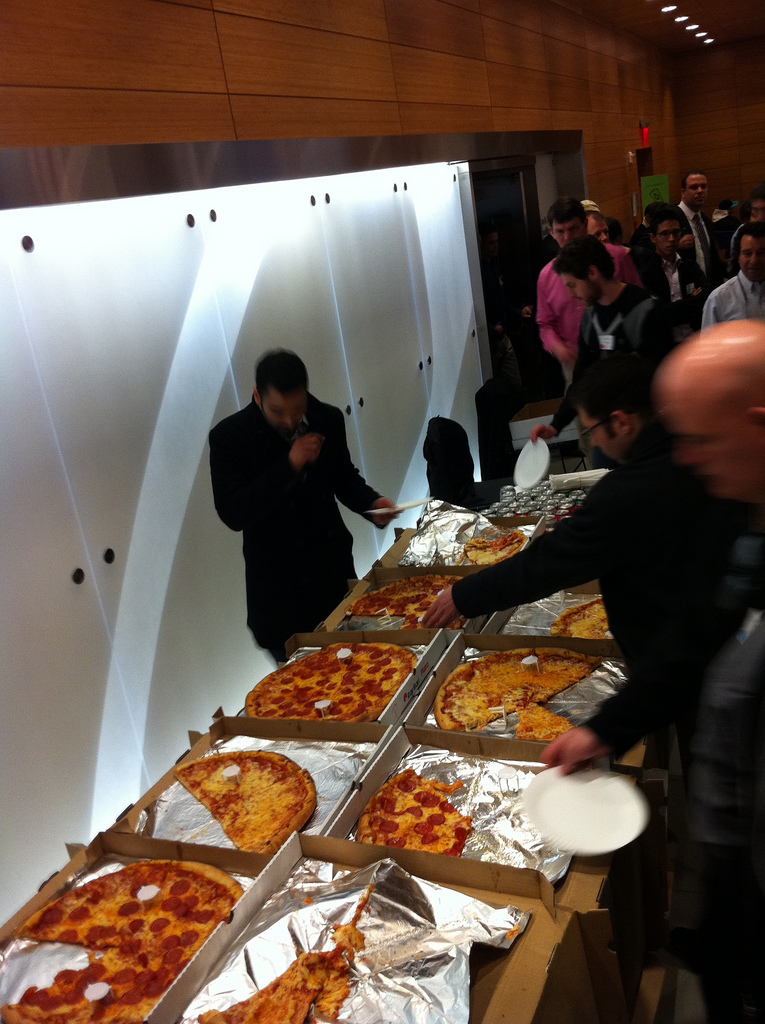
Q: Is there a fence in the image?
A: No, there are no fences.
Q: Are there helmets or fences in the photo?
A: No, there are no fences or helmets.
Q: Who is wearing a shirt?
A: The man is wearing a shirt.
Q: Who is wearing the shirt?
A: The man is wearing a shirt.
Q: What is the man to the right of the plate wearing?
A: The man is wearing a shirt.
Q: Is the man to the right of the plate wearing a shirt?
A: Yes, the man is wearing a shirt.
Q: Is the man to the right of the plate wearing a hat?
A: No, the man is wearing a shirt.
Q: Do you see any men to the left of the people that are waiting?
A: Yes, there is a man to the left of the people.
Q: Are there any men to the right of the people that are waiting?
A: No, the man is to the left of the people.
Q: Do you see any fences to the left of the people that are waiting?
A: No, there is a man to the left of the people.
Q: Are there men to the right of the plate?
A: Yes, there is a man to the right of the plate.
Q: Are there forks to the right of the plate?
A: No, there is a man to the right of the plate.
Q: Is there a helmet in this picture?
A: No, there are no helmets.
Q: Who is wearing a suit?
A: The man is wearing a suit.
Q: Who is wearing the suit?
A: The man is wearing a suit.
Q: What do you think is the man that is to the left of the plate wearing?
A: The man is wearing a suit.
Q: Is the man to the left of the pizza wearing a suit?
A: Yes, the man is wearing a suit.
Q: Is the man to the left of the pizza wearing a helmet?
A: No, the man is wearing a suit.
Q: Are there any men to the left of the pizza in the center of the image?
A: Yes, there is a man to the left of the pizza.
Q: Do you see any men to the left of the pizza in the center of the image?
A: Yes, there is a man to the left of the pizza.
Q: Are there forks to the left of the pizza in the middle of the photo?
A: No, there is a man to the left of the pizza.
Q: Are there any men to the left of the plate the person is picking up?
A: Yes, there is a man to the left of the plate.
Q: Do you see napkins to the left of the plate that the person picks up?
A: No, there is a man to the left of the plate.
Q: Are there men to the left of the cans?
A: Yes, there is a man to the left of the cans.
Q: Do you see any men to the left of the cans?
A: Yes, there is a man to the left of the cans.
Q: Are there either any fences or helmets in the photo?
A: No, there are no fences or helmets.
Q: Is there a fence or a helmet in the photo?
A: No, there are no fences or helmets.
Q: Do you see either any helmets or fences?
A: No, there are no fences or helmets.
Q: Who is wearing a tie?
A: The man is wearing a tie.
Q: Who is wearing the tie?
A: The man is wearing a tie.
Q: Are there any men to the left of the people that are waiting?
A: Yes, there is a man to the left of the people.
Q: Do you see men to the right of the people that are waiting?
A: No, the man is to the left of the people.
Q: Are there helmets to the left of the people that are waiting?
A: No, there is a man to the left of the people.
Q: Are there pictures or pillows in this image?
A: No, there are no pictures or pillows.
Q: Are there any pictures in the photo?
A: No, there are no pictures.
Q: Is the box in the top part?
A: No, the box is in the bottom of the image.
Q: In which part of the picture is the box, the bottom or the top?
A: The box is in the bottom of the image.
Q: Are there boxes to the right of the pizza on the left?
A: Yes, there is a box to the right of the pizza.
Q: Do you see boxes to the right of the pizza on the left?
A: Yes, there is a box to the right of the pizza.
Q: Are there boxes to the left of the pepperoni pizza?
A: No, the box is to the right of the pizza.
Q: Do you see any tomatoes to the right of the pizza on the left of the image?
A: No, there is a box to the right of the pizza.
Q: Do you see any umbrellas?
A: No, there are no umbrellas.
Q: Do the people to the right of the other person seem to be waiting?
A: Yes, the people are waiting.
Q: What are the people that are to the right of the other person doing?
A: The people are waiting.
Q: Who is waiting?
A: The people are waiting.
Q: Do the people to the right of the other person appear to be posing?
A: No, the people are waiting.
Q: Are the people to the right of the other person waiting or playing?
A: The people are waiting.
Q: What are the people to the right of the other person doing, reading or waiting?
A: The people are waiting.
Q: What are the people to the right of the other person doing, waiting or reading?
A: The people are waiting.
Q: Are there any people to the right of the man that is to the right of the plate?
A: Yes, there are people to the right of the man.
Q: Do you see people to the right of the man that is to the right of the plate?
A: Yes, there are people to the right of the man.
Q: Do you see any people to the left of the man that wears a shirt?
A: No, the people are to the right of the man.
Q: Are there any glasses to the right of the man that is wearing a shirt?
A: No, there are people to the right of the man.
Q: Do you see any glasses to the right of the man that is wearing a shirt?
A: No, there are people to the right of the man.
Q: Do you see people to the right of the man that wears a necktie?
A: Yes, there are people to the right of the man.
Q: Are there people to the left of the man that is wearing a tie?
A: No, the people are to the right of the man.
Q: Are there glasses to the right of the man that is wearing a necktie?
A: No, there are people to the right of the man.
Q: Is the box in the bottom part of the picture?
A: Yes, the box is in the bottom of the image.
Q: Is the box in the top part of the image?
A: No, the box is in the bottom of the image.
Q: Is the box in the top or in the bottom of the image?
A: The box is in the bottom of the image.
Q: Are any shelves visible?
A: No, there are no shelves.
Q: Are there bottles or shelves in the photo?
A: No, there are no shelves or bottles.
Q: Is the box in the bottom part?
A: Yes, the box is in the bottom of the image.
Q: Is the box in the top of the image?
A: No, the box is in the bottom of the image.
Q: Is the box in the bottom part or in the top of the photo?
A: The box is in the bottom of the image.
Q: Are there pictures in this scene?
A: No, there are no pictures.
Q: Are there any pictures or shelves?
A: No, there are no pictures or shelves.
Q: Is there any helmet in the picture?
A: No, there are no helmets.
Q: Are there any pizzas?
A: Yes, there is a pizza.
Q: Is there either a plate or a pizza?
A: Yes, there is a pizza.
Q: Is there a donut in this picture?
A: No, there are no donuts.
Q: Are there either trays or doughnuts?
A: No, there are no doughnuts or trays.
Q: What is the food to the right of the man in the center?
A: The food is a pizza.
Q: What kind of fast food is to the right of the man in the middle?
A: The food is a pizza.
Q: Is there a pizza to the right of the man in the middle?
A: Yes, there is a pizza to the right of the man.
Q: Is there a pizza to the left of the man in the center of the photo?
A: No, the pizza is to the right of the man.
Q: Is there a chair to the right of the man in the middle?
A: No, there is a pizza to the right of the man.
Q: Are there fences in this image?
A: No, there are no fences.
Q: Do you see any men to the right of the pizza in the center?
A: Yes, there is a man to the right of the pizza.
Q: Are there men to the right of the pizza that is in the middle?
A: Yes, there is a man to the right of the pizza.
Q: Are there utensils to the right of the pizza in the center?
A: No, there is a man to the right of the pizza.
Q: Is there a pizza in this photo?
A: Yes, there is a pizza.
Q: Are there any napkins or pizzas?
A: Yes, there is a pizza.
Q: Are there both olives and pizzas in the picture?
A: No, there is a pizza but no olives.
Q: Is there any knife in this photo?
A: No, there are no knives.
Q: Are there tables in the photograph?
A: Yes, there is a table.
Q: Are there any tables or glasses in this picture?
A: Yes, there is a table.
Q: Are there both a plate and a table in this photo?
A: Yes, there are both a table and a plate.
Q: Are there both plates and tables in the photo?
A: Yes, there are both a table and a plate.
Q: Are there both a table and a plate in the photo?
A: Yes, there are both a table and a plate.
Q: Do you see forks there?
A: No, there are no forks.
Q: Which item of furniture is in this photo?
A: The piece of furniture is a table.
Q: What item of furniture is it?
A: The piece of furniture is a table.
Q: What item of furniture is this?
A: This is a table.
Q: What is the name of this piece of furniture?
A: This is a table.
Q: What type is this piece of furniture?
A: This is a table.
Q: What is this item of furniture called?
A: This is a table.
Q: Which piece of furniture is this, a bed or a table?
A: This is a table.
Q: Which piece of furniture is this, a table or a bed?
A: This is a table.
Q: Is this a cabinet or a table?
A: This is a table.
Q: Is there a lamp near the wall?
A: No, there is a table near the wall.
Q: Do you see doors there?
A: Yes, there is a door.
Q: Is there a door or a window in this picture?
A: Yes, there is a door.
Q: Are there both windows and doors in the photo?
A: No, there is a door but no windows.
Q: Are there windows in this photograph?
A: No, there are no windows.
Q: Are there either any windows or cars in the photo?
A: No, there are no windows or cars.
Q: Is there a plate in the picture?
A: Yes, there is a plate.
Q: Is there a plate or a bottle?
A: Yes, there is a plate.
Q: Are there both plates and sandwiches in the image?
A: No, there is a plate but no sandwiches.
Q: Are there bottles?
A: No, there are no bottles.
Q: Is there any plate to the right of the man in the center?
A: Yes, there is a plate to the right of the man.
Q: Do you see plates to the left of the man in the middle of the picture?
A: No, the plate is to the right of the man.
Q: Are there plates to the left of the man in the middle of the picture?
A: No, the plate is to the right of the man.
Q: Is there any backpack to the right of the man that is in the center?
A: No, there is a plate to the right of the man.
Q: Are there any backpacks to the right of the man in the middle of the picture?
A: No, there is a plate to the right of the man.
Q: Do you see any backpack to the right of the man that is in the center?
A: No, there is a plate to the right of the man.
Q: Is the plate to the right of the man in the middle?
A: Yes, the plate is to the right of the man.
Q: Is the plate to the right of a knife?
A: No, the plate is to the right of the man.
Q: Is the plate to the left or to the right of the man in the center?
A: The plate is to the right of the man.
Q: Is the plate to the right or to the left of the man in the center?
A: The plate is to the right of the man.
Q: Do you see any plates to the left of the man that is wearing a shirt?
A: Yes, there is a plate to the left of the man.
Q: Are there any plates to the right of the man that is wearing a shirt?
A: No, the plate is to the left of the man.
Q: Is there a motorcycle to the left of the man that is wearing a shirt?
A: No, there is a plate to the left of the man.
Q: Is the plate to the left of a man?
A: Yes, the plate is to the left of a man.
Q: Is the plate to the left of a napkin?
A: No, the plate is to the left of a man.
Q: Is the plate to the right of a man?
A: No, the plate is to the left of a man.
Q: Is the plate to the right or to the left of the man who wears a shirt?
A: The plate is to the left of the man.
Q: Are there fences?
A: No, there are no fences.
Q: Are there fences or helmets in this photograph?
A: No, there are no fences or helmets.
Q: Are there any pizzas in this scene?
A: Yes, there is a pizza.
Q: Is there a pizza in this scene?
A: Yes, there is a pizza.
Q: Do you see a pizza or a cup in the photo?
A: Yes, there is a pizza.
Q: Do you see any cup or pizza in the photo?
A: Yes, there is a pizza.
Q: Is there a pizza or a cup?
A: Yes, there is a pizza.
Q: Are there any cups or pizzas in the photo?
A: Yes, there is a pizza.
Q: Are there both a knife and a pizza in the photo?
A: No, there is a pizza but no knives.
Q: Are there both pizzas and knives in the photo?
A: No, there is a pizza but no knives.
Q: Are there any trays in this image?
A: No, there are no trays.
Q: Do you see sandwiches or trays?
A: No, there are no trays or sandwiches.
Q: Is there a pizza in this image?
A: Yes, there is a pizza.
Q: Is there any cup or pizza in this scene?
A: Yes, there is a pizza.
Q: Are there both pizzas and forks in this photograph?
A: No, there is a pizza but no forks.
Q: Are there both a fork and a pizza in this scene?
A: No, there is a pizza but no forks.